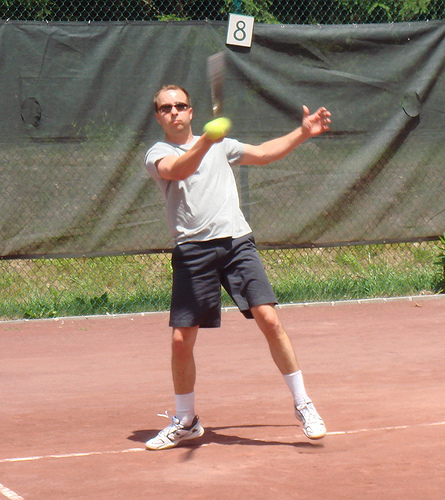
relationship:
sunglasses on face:
[157, 98, 195, 115] [156, 74, 204, 124]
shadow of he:
[126, 419, 321, 455] [142, 81, 329, 451]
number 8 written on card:
[232, 19, 247, 41] [224, 12, 253, 50]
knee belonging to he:
[173, 334, 194, 349] [142, 81, 329, 451]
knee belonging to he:
[245, 307, 295, 330] [142, 81, 329, 451]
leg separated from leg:
[166, 259, 206, 429] [223, 250, 312, 403]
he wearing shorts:
[142, 81, 329, 451] [168, 230, 278, 327]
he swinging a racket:
[142, 81, 329, 451] [193, 44, 248, 144]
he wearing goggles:
[142, 81, 329, 451] [159, 101, 191, 118]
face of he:
[155, 91, 190, 133] [142, 81, 329, 451]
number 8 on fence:
[234, 19, 247, 41] [1, 24, 439, 244]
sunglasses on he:
[157, 98, 195, 115] [142, 81, 329, 451]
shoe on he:
[290, 396, 328, 443] [142, 81, 329, 451]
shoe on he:
[140, 410, 206, 453] [142, 81, 329, 451]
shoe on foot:
[290, 396, 328, 443] [295, 406, 324, 438]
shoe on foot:
[140, 410, 206, 453] [142, 422, 202, 448]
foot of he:
[295, 406, 324, 438] [142, 81, 329, 451]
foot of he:
[142, 422, 202, 448] [142, 81, 329, 451]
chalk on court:
[2, 290, 442, 498] [3, 1, 444, 498]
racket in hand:
[206, 51, 226, 117] [298, 102, 331, 136]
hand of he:
[298, 102, 331, 136] [142, 81, 329, 451]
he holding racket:
[142, 81, 329, 451] [206, 51, 226, 117]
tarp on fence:
[0, 20, 442, 257] [4, 3, 443, 287]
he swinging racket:
[142, 81, 329, 451] [205, 51, 226, 140]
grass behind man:
[269, 242, 440, 299] [115, 67, 358, 461]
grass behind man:
[0, 259, 165, 317] [115, 67, 358, 461]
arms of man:
[144, 97, 347, 180] [115, 67, 358, 461]